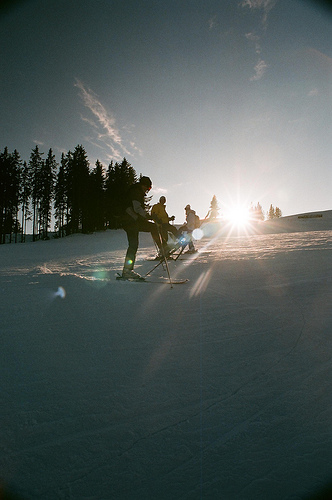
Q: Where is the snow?
A: On the ground.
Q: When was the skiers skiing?
A: Sundown.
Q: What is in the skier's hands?
A: Ski poles.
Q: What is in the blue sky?
A: Small clouds.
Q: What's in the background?
A: Trees.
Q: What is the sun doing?
A: Setting.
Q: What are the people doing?
A: Skiing.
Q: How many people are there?
A: Three.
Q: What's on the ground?
A: Snow.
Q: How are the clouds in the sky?
A: Thin.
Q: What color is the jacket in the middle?
A: Yellow.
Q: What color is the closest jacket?
A: Black and white.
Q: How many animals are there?
A: None.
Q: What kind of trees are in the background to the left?
A: Evergreen.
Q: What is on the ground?
A: Snow.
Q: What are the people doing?
A: Skiing.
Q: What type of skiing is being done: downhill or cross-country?
A: Cross-country.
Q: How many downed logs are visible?
A: One.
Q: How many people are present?
A: Three.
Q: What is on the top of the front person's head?
A: Hat.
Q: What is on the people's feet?
A: Skis.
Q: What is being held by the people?
A: Ski poles.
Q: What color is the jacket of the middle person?
A: Yellow.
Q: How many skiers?
A: Three.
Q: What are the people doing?
A: Skiing.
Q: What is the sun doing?
A: Setting.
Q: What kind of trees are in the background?
A: Pine tree.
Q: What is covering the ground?
A: Snow.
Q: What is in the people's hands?
A: Ski poles.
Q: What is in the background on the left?
A: Trees.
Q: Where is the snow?
A: On the ground.